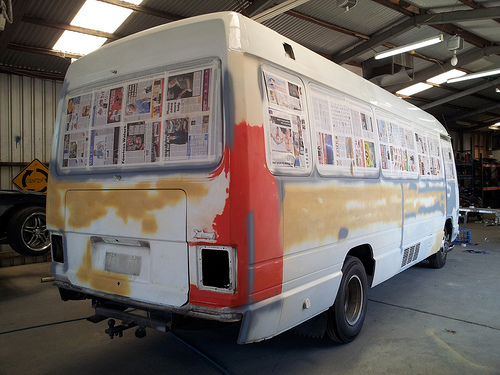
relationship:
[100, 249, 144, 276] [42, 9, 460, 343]
license plate on van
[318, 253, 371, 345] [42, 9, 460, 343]
tire on van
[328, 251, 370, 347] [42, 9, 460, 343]
wheel on van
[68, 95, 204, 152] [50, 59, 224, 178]
newspaper covering back window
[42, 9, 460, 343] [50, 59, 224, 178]
van has back window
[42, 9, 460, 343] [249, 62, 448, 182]
van has side windows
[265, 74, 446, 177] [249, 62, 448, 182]
newspaper covering side windows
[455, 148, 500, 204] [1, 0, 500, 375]
shelves inside building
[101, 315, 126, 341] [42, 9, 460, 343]
towing hitch on van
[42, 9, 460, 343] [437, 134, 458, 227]
van has front side door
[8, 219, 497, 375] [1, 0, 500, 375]
floor inside building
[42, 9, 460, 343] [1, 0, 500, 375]
van under building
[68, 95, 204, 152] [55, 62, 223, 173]
newspaper sticking to mirror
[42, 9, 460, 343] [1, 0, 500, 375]
van parked in building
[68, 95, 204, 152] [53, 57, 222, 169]
newspaper on window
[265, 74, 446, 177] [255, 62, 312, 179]
newspaper on side windows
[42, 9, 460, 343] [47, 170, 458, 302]
van has fainted paint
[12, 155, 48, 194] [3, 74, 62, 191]
board posted to wall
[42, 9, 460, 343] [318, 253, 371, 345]
van has tire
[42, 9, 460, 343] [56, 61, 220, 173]
van has rear window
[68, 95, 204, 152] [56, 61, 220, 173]
newspaper attached to rear window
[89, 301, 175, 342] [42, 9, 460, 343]
trailer hitch attached to van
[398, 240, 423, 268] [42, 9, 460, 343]
air vents on side of van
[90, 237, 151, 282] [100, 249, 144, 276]
area for license plate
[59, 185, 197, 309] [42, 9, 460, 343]
access door on back of van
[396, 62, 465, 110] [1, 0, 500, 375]
sky lights built into roof of building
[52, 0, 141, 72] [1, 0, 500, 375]
sky lights built into roof of building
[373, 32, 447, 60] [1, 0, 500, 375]
light in building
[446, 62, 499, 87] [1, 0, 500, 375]
light in building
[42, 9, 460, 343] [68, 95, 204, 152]
van covered in newspaper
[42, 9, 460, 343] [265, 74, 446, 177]
van covered in newspaper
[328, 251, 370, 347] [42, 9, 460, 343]
wheel on side of van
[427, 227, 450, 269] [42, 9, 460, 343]
wheel on side of van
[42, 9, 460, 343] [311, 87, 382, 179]
van has side window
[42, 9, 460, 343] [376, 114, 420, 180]
van has side window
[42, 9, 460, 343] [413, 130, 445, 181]
van has side window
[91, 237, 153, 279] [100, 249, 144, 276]
holder for license plate